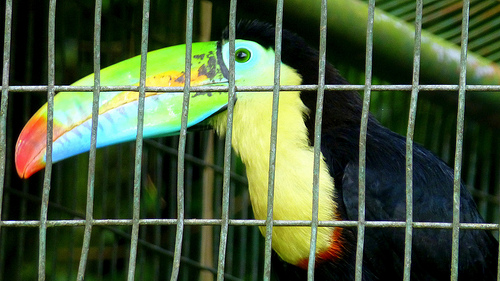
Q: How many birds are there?
A: One.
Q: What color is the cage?
A: Gray.